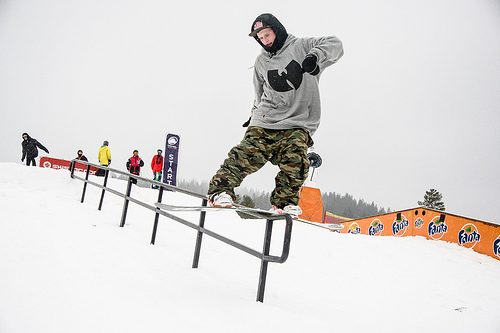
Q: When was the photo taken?
A: Daytime.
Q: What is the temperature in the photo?
A: Cold.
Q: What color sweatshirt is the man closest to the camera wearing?
A: Gray.